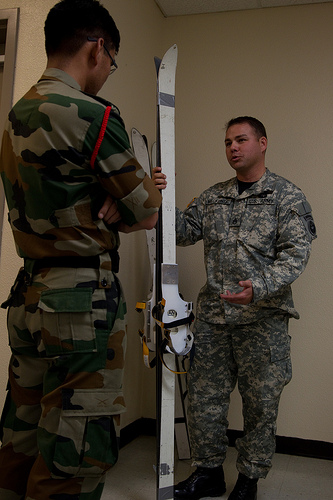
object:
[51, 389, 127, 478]
pocket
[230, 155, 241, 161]
mouth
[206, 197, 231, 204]
name tape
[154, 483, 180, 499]
stripe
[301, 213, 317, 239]
emblem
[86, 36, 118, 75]
glasses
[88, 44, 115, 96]
face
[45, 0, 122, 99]
head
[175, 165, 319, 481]
uniform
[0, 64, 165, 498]
uniform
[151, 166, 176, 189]
hand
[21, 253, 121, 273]
belt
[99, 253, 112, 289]
loop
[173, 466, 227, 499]
boots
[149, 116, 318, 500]
soldier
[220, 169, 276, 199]
collar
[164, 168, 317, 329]
shirt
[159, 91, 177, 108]
tape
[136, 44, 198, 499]
skis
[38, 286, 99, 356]
pocket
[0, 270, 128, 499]
pants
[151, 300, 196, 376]
boot straps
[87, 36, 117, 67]
eyeglass arm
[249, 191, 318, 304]
sleeve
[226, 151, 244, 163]
talking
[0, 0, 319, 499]
two men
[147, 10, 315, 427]
wall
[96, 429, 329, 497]
floor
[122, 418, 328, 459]
floor base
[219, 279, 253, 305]
hand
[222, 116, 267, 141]
man's hair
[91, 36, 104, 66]
ear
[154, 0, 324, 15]
ceiling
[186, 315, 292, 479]
military pants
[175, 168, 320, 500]
military uniforms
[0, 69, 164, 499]
military uniforms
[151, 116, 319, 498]
man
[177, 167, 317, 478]
suit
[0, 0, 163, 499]
man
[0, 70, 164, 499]
suit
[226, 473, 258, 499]
boots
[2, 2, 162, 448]
wall